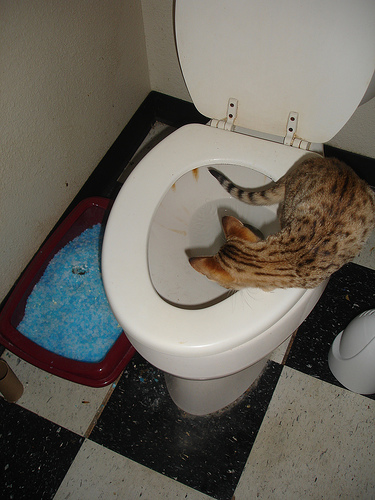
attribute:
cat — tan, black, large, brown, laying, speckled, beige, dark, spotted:
[183, 153, 374, 297]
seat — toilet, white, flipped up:
[97, 117, 342, 354]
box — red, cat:
[1, 194, 138, 385]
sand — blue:
[21, 218, 120, 359]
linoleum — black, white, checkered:
[4, 120, 374, 495]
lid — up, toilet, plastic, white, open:
[161, 0, 364, 153]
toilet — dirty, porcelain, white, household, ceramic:
[100, 0, 374, 426]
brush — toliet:
[328, 309, 375, 401]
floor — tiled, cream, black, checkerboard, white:
[3, 109, 369, 489]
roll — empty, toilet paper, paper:
[1, 354, 29, 401]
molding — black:
[88, 89, 375, 203]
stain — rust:
[175, 169, 200, 192]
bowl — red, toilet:
[97, 116, 346, 411]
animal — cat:
[188, 145, 373, 299]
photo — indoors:
[7, 11, 374, 490]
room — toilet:
[3, 0, 374, 498]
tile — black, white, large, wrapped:
[86, 359, 288, 494]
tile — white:
[52, 442, 220, 499]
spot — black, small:
[75, 397, 95, 412]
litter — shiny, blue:
[16, 224, 103, 355]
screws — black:
[224, 90, 302, 137]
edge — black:
[84, 90, 371, 204]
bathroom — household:
[6, 0, 374, 497]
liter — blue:
[16, 219, 143, 355]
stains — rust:
[169, 161, 204, 197]